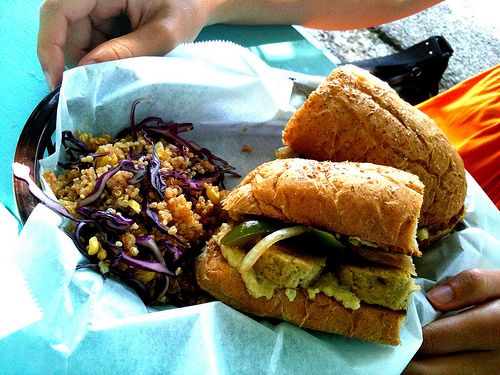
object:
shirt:
[413, 62, 500, 211]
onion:
[239, 225, 306, 274]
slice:
[119, 251, 176, 276]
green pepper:
[220, 219, 380, 248]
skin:
[220, 217, 270, 245]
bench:
[292, 0, 500, 93]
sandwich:
[195, 157, 426, 346]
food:
[41, 97, 243, 307]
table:
[0, 0, 500, 375]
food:
[275, 63, 469, 247]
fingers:
[399, 349, 498, 375]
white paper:
[0, 39, 500, 375]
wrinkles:
[437, 66, 500, 188]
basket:
[13, 82, 62, 225]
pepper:
[302, 226, 345, 250]